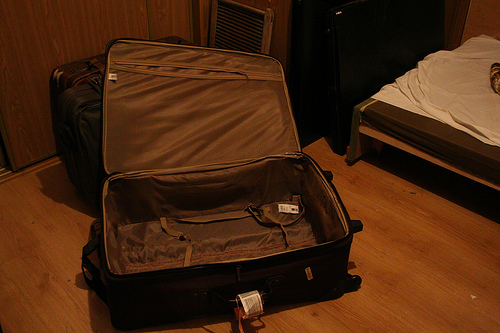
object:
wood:
[0, 0, 21, 24]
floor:
[0, 132, 500, 332]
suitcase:
[80, 37, 363, 331]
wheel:
[349, 273, 361, 288]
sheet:
[370, 33, 500, 148]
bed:
[343, 34, 500, 192]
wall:
[2, 1, 191, 172]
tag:
[236, 290, 264, 320]